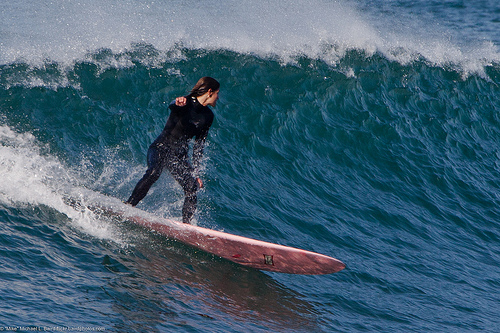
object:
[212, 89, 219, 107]
face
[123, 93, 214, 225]
wetsuit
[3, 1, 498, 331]
picture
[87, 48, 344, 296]
woman surfing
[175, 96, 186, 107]
hand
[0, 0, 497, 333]
outdoor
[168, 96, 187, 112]
arm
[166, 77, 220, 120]
hair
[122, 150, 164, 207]
leg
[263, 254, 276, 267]
logo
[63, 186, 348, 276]
surfboard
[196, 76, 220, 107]
head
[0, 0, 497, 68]
crest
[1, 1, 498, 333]
ocean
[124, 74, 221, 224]
woman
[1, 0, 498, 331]
water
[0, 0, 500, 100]
wave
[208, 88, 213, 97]
ear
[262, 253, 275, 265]
sticker